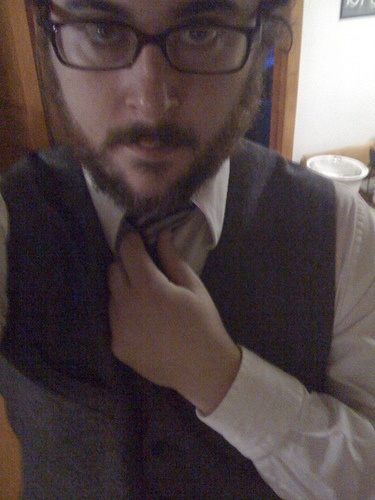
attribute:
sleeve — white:
[205, 360, 361, 493]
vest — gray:
[6, 137, 354, 499]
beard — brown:
[90, 82, 232, 228]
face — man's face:
[49, 2, 265, 195]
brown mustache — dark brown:
[107, 119, 201, 150]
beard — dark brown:
[75, 130, 230, 222]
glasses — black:
[30, 2, 266, 76]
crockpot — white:
[301, 152, 371, 201]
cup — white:
[306, 153, 370, 192]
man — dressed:
[0, 1, 372, 499]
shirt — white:
[0, 150, 374, 498]